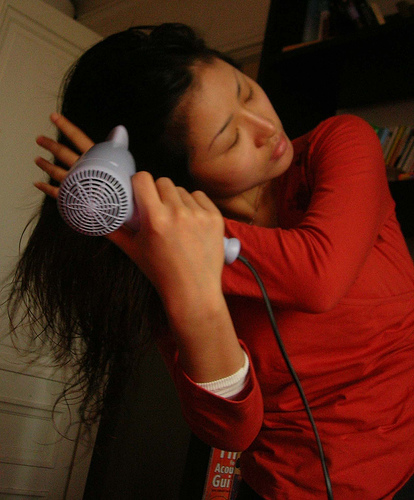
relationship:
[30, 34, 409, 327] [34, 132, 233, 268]
girl holding hair dryer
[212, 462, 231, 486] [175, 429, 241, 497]
lettering printed on book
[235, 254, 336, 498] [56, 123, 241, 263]
cord attached to hair dryer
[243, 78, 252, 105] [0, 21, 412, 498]
eye part of girl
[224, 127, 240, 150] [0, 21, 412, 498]
eye part of girl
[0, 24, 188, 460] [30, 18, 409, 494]
long hair part of woman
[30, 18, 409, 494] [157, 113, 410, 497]
woman wearing shirt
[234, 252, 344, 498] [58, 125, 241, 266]
cord attached to blow dryer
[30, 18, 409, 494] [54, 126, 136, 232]
woman holding blow dryer